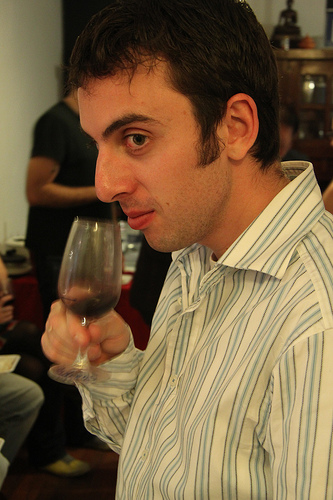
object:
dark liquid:
[66, 291, 118, 322]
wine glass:
[48, 216, 123, 386]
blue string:
[172, 379, 175, 382]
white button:
[168, 374, 180, 387]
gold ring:
[47, 326, 53, 334]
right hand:
[41, 298, 131, 370]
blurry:
[69, 215, 120, 242]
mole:
[166, 202, 170, 205]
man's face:
[78, 94, 229, 254]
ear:
[224, 92, 260, 160]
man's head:
[66, 0, 282, 253]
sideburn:
[195, 100, 228, 167]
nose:
[95, 143, 138, 203]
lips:
[122, 207, 157, 230]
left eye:
[124, 133, 151, 149]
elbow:
[25, 180, 53, 207]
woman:
[24, 67, 127, 474]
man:
[40, 0, 333, 499]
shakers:
[300, 75, 329, 105]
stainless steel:
[306, 92, 312, 97]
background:
[0, 1, 333, 499]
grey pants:
[0, 369, 46, 489]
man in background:
[0, 354, 47, 498]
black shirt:
[24, 101, 111, 254]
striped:
[193, 397, 244, 499]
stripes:
[292, 257, 326, 318]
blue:
[301, 335, 321, 496]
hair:
[62, 0, 280, 177]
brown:
[219, 28, 254, 64]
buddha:
[270, 1, 305, 48]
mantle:
[270, 72, 332, 183]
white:
[172, 373, 178, 379]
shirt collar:
[171, 161, 329, 281]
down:
[171, 159, 230, 253]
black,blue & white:
[225, 406, 248, 448]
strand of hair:
[127, 67, 137, 97]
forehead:
[78, 60, 170, 132]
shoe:
[46, 454, 92, 477]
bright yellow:
[54, 462, 63, 470]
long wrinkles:
[1, 384, 45, 417]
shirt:
[49, 160, 333, 500]